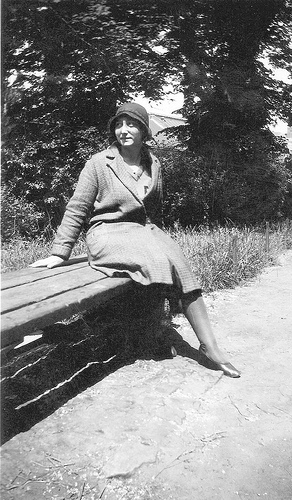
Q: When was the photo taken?
A: Daytime.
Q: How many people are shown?
A: One.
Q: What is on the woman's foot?
A: Shoe.